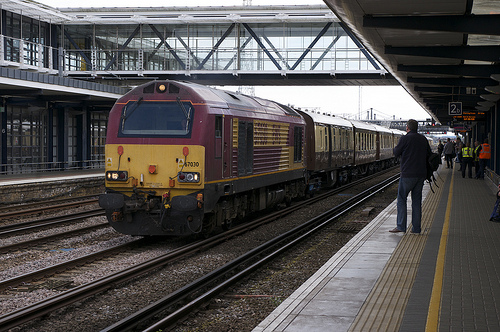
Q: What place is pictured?
A: It is a station.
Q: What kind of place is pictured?
A: It is a station.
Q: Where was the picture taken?
A: It was taken at the station.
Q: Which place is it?
A: It is a station.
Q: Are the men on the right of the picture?
A: Yes, the men are on the right of the image.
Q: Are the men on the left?
A: No, the men are on the right of the image.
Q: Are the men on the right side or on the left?
A: The men are on the right of the image.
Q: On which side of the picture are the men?
A: The men are on the right of the image.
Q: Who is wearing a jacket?
A: The men are wearing a jacket.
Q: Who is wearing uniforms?
A: The men are wearing uniforms.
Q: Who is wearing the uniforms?
A: The men are wearing uniforms.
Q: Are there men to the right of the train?
A: Yes, there are men to the right of the train.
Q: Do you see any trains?
A: Yes, there is a train.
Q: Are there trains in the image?
A: Yes, there is a train.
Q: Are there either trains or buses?
A: Yes, there is a train.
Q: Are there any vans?
A: No, there are no vans.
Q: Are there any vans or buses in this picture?
A: No, there are no vans or buses.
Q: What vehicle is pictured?
A: The vehicle is a train.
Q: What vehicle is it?
A: The vehicle is a train.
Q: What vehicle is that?
A: This is a train.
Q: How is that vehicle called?
A: This is a train.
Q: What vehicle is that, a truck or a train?
A: This is a train.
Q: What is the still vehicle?
A: The vehicle is a train.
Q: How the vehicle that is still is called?
A: The vehicle is a train.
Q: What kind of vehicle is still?
A: The vehicle is a train.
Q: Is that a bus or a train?
A: That is a train.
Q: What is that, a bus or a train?
A: That is a train.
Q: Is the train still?
A: Yes, the train is still.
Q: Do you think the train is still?
A: Yes, the train is still.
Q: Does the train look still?
A: Yes, the train is still.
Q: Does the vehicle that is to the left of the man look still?
A: Yes, the train is still.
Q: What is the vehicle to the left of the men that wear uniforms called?
A: The vehicle is a train.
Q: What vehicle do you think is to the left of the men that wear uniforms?
A: The vehicle is a train.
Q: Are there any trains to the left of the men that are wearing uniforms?
A: Yes, there is a train to the left of the men.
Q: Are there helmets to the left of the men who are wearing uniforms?
A: No, there is a train to the left of the men.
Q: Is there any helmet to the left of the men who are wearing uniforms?
A: No, there is a train to the left of the men.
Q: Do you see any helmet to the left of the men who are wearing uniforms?
A: No, there is a train to the left of the men.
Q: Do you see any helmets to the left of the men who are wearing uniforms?
A: No, there is a train to the left of the men.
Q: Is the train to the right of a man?
A: No, the train is to the left of a man.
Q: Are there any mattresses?
A: No, there are no mattresses.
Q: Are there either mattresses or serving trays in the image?
A: No, there are no mattresses or serving trays.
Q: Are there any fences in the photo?
A: No, there are no fences.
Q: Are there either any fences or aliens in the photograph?
A: No, there are no fences or aliens.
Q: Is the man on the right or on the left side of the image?
A: The man is on the right of the image.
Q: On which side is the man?
A: The man is on the right of the image.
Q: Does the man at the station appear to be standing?
A: Yes, the man is standing.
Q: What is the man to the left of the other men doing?
A: The man is standing.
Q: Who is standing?
A: The man is standing.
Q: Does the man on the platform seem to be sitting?
A: No, the man is standing.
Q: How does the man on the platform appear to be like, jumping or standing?
A: The man is standing.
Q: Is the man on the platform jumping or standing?
A: The man is standing.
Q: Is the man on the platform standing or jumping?
A: The man is standing.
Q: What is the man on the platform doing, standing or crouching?
A: The man is standing.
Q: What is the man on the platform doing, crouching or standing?
A: The man is standing.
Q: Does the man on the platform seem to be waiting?
A: Yes, the man is waiting.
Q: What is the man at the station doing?
A: The man is waiting.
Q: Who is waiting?
A: The man is waiting.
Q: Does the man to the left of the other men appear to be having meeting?
A: No, the man is waiting.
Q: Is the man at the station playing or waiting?
A: The man is waiting.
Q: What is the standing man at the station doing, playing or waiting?
A: The man is waiting.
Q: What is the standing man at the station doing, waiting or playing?
A: The man is waiting.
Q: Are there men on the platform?
A: Yes, there is a man on the platform.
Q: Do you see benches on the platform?
A: No, there is a man on the platform.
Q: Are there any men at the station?
A: Yes, there is a man at the station.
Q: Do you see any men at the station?
A: Yes, there is a man at the station.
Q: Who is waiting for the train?
A: The man is waiting for the train.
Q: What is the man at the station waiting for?
A: The man is waiting for the train.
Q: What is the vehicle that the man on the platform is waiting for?
A: The vehicle is a train.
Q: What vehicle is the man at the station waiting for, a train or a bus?
A: The man is waiting for a train.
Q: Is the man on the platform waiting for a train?
A: Yes, the man is waiting for a train.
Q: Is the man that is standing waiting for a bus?
A: No, the man is waiting for a train.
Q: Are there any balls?
A: No, there are no balls.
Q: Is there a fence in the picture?
A: No, there are no fences.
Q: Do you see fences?
A: No, there are no fences.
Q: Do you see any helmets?
A: No, there are no helmets.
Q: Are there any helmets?
A: No, there are no helmets.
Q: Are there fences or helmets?
A: No, there are no helmets or fences.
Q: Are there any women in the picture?
A: No, there are no women.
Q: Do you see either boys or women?
A: No, there are no women or boys.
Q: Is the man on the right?
A: Yes, the man is on the right of the image.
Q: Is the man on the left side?
A: No, the man is on the right of the image.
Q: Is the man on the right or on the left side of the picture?
A: The man is on the right of the image.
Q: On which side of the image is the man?
A: The man is on the right of the image.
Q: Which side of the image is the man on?
A: The man is on the right of the image.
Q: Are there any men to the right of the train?
A: Yes, there is a man to the right of the train.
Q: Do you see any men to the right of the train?
A: Yes, there is a man to the right of the train.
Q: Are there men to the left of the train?
A: No, the man is to the right of the train.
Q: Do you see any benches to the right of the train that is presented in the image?
A: No, there is a man to the right of the train.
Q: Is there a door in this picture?
A: Yes, there is a door.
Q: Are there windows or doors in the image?
A: Yes, there is a door.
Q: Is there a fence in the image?
A: No, there are no fences.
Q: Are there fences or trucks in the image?
A: No, there are no fences or trucks.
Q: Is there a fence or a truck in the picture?
A: No, there are no fences or trucks.